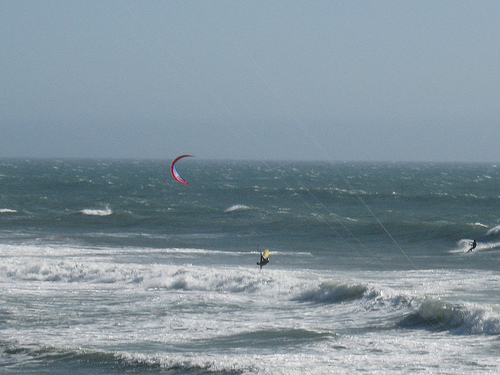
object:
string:
[114, 0, 500, 375]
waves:
[277, 276, 483, 324]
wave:
[296, 259, 423, 324]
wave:
[1, 259, 498, 334]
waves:
[169, 260, 317, 298]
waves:
[2, 253, 99, 283]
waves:
[123, 345, 250, 371]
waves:
[0, 242, 94, 258]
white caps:
[35, 151, 148, 202]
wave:
[69, 205, 133, 220]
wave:
[220, 202, 257, 212]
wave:
[0, 205, 16, 214]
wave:
[424, 217, 499, 239]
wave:
[266, 186, 499, 202]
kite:
[171, 155, 196, 186]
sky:
[0, 0, 500, 163]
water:
[1, 160, 498, 350]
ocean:
[0, 160, 500, 374]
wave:
[58, 203, 142, 230]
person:
[257, 247, 271, 265]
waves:
[53, 223, 496, 347]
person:
[467, 239, 477, 252]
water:
[0, 158, 500, 375]